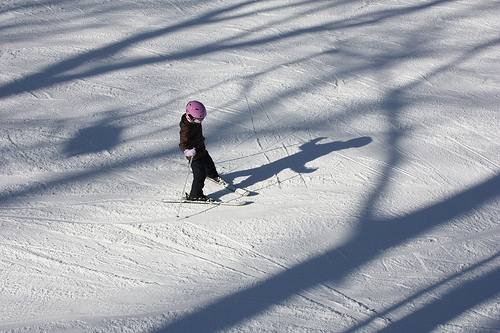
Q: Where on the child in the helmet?
A: Head.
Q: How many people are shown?
A: One.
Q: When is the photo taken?
A: Daytime.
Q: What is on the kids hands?
A: Gloves.